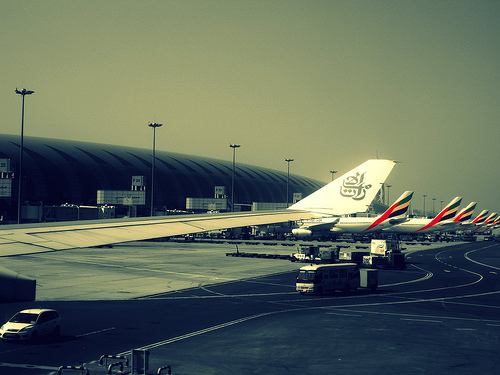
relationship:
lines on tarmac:
[426, 249, 500, 310] [398, 238, 500, 372]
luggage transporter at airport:
[288, 238, 386, 266] [4, 124, 320, 222]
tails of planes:
[380, 190, 499, 242] [322, 185, 498, 239]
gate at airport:
[98, 176, 149, 209] [4, 124, 320, 222]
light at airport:
[15, 79, 35, 107] [4, 124, 320, 222]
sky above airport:
[8, 12, 478, 124] [4, 124, 320, 222]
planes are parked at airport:
[322, 185, 498, 239] [4, 124, 320, 222]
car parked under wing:
[3, 306, 69, 341] [7, 198, 319, 256]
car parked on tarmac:
[3, 306, 69, 341] [398, 238, 500, 372]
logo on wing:
[343, 171, 372, 201] [7, 198, 319, 256]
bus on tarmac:
[291, 260, 366, 300] [398, 238, 500, 372]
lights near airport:
[13, 88, 338, 177] [4, 124, 320, 222]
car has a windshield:
[3, 306, 69, 341] [11, 311, 41, 326]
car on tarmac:
[3, 306, 69, 341] [398, 238, 500, 372]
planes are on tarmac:
[322, 185, 498, 239] [398, 238, 500, 372]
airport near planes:
[4, 124, 320, 222] [322, 185, 498, 239]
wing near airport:
[7, 198, 319, 256] [4, 124, 320, 222]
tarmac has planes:
[398, 238, 500, 372] [322, 185, 498, 239]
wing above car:
[7, 198, 319, 256] [3, 306, 69, 341]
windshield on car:
[11, 311, 41, 326] [3, 306, 69, 341]